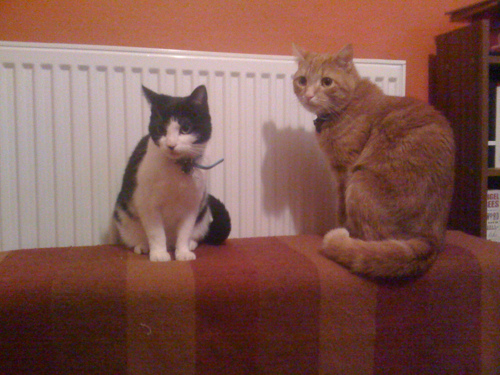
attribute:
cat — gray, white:
[112, 69, 231, 265]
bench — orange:
[26, 245, 482, 351]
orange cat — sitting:
[288, 41, 458, 282]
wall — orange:
[32, 3, 470, 90]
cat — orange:
[252, 45, 492, 318]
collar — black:
[173, 151, 234, 177]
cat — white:
[94, 79, 238, 266]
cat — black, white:
[96, 83, 252, 268]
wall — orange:
[1, 3, 443, 182]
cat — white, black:
[78, 59, 447, 272]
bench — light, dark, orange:
[11, 207, 496, 367]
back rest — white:
[5, 40, 404, 248]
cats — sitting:
[72, 27, 468, 284]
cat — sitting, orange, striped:
[286, 41, 453, 278]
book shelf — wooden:
[425, 12, 498, 245]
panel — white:
[1, 41, 406, 252]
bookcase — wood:
[433, 21, 498, 240]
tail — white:
[202, 189, 239, 270]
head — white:
[142, 85, 214, 165]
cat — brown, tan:
[279, 53, 476, 290]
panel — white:
[54, 33, 416, 260]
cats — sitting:
[112, 34, 459, 279]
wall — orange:
[92, 8, 333, 50]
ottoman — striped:
[2, 224, 498, 371]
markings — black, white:
[164, 110, 202, 146]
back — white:
[4, 37, 416, 253]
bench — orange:
[6, 226, 498, 373]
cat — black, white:
[106, 79, 236, 268]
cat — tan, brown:
[282, 37, 462, 282]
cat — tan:
[295, 56, 445, 233]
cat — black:
[86, 78, 216, 249]